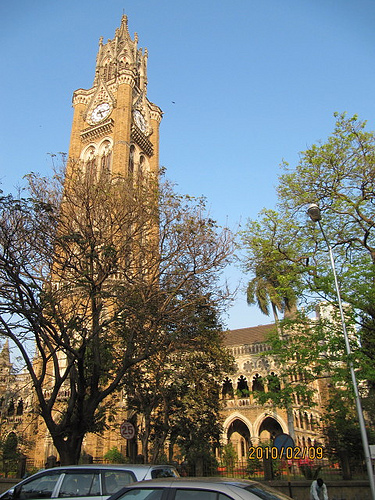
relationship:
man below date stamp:
[308, 474, 329, 499] [244, 440, 325, 464]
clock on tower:
[84, 100, 112, 128] [47, 9, 159, 456]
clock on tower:
[130, 109, 147, 134] [47, 9, 159, 456]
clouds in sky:
[195, 107, 225, 126] [1, 0, 354, 88]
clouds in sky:
[0, 1, 375, 374] [1, 0, 370, 372]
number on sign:
[120, 425, 133, 433] [117, 420, 138, 441]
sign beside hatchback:
[112, 418, 138, 441] [0, 464, 180, 498]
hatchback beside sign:
[0, 464, 180, 498] [241, 428, 343, 476]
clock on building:
[86, 100, 118, 128] [35, 10, 163, 472]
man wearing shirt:
[286, 454, 329, 496] [312, 479, 328, 498]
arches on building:
[221, 411, 254, 469] [159, 327, 341, 485]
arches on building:
[252, 409, 297, 469] [159, 327, 341, 485]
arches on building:
[251, 369, 265, 394] [159, 327, 341, 485]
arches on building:
[265, 368, 283, 392] [159, 327, 341, 485]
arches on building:
[235, 373, 249, 396] [159, 327, 341, 485]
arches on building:
[219, 373, 235, 397] [159, 327, 341, 485]